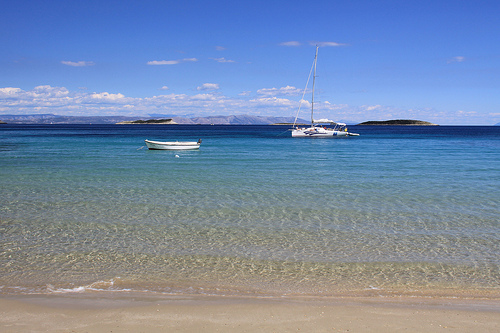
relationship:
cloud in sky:
[147, 59, 179, 65] [0, 0, 499, 126]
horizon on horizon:
[0, 114, 357, 127] [0, 113, 315, 124]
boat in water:
[143, 136, 202, 152] [0, 125, 499, 300]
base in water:
[291, 41, 359, 137] [0, 125, 499, 300]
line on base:
[291, 43, 320, 128] [291, 41, 359, 137]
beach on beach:
[1, 279, 498, 332] [1, 279, 498, 332]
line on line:
[292, 58, 314, 127] [291, 43, 320, 128]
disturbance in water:
[173, 154, 180, 159] [0, 125, 499, 300]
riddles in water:
[1, 185, 499, 288] [0, 125, 499, 300]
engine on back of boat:
[197, 137, 202, 144] [143, 136, 202, 152]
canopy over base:
[312, 118, 347, 129] [291, 41, 359, 137]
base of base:
[291, 129, 360, 137] [291, 41, 359, 137]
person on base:
[344, 127, 348, 132] [291, 41, 359, 137]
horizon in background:
[0, 114, 357, 127] [0, 0, 498, 126]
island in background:
[355, 118, 441, 125] [0, 0, 498, 126]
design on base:
[302, 129, 328, 136] [291, 41, 359, 137]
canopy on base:
[312, 118, 347, 129] [291, 41, 359, 137]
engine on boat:
[197, 137, 202, 144] [143, 136, 202, 152]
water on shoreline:
[0, 262, 499, 296] [1, 279, 498, 332]